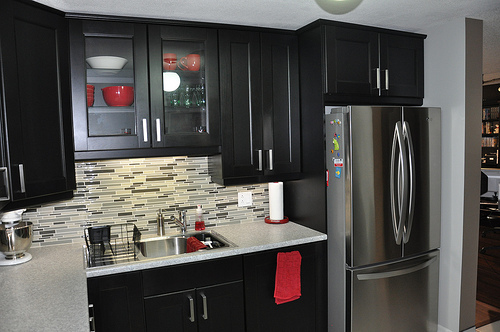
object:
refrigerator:
[344, 105, 440, 332]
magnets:
[330, 119, 343, 179]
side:
[326, 108, 347, 332]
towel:
[274, 251, 302, 305]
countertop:
[241, 228, 292, 238]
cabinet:
[148, 24, 221, 148]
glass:
[163, 39, 207, 134]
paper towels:
[268, 182, 284, 220]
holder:
[265, 215, 289, 224]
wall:
[99, 159, 203, 204]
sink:
[135, 232, 230, 260]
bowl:
[86, 55, 129, 69]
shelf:
[86, 69, 135, 83]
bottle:
[195, 205, 206, 231]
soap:
[195, 221, 205, 231]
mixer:
[0, 221, 32, 267]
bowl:
[0, 220, 33, 266]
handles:
[388, 121, 415, 246]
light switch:
[237, 192, 252, 207]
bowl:
[101, 86, 135, 107]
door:
[344, 105, 402, 269]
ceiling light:
[313, 0, 362, 15]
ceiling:
[385, 4, 457, 19]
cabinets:
[68, 19, 223, 159]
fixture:
[314, 0, 362, 15]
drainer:
[83, 222, 142, 268]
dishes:
[85, 56, 134, 107]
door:
[69, 19, 150, 152]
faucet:
[170, 209, 188, 233]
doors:
[345, 106, 442, 269]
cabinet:
[17, 269, 50, 285]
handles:
[142, 118, 161, 142]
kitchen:
[0, 0, 500, 332]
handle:
[279, 255, 299, 259]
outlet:
[238, 191, 253, 207]